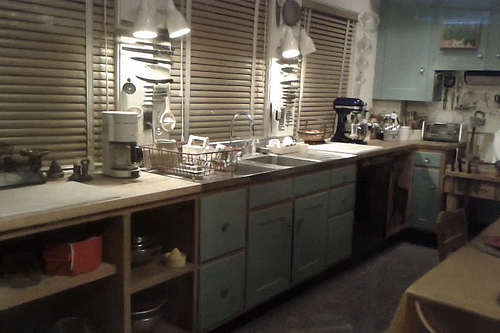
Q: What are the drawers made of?
A: Wood.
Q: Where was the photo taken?
A: Kitchen.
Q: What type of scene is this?
A: Indoor.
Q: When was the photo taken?
A: Nighttime.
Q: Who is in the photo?
A: No one.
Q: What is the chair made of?
A: Wood.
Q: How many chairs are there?
A: One.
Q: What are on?
A: Lights.